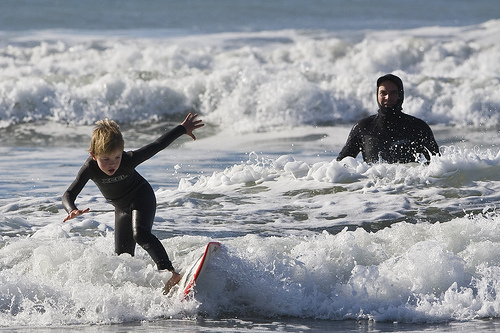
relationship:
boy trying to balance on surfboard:
[62, 113, 204, 287] [172, 239, 221, 304]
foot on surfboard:
[164, 271, 185, 295] [145, 235, 220, 292]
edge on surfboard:
[182, 241, 221, 303] [173, 235, 229, 305]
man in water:
[336, 70, 440, 162] [0, 1, 497, 331]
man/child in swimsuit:
[60, 71, 468, 311] [62, 125, 187, 270]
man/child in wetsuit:
[60, 71, 468, 311] [360, 121, 428, 149]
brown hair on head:
[86, 117, 125, 159] [86, 117, 126, 177]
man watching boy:
[336, 70, 440, 162] [62, 113, 204, 287]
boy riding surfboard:
[62, 113, 204, 287] [112, 255, 245, 312]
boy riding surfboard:
[65, 116, 204, 268] [175, 240, 219, 286]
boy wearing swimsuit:
[62, 113, 204, 287] [36, 87, 221, 307]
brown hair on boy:
[91, 123, 123, 155] [62, 113, 204, 287]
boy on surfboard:
[62, 113, 204, 287] [93, 230, 237, 330]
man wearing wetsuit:
[336, 70, 440, 162] [334, 114, 429, 166]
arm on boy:
[58, 167, 91, 222] [62, 113, 204, 287]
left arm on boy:
[132, 118, 178, 168] [60, 109, 202, 299]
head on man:
[377, 75, 404, 112] [336, 70, 440, 162]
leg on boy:
[129, 179, 189, 295] [32, 109, 213, 278]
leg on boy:
[101, 203, 142, 279] [72, 120, 236, 265]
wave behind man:
[14, 39, 496, 122] [336, 70, 440, 162]